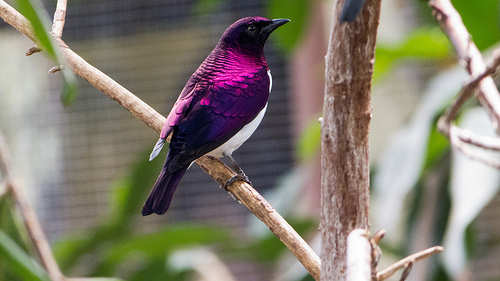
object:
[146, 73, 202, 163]
wing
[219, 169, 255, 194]
foot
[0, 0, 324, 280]
branch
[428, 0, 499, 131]
branch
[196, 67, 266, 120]
wing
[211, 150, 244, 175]
leg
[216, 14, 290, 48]
head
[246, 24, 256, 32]
eye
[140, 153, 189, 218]
tail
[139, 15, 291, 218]
bird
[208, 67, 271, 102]
breast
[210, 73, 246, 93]
feathers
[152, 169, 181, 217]
feathers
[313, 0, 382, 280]
stalk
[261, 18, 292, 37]
beak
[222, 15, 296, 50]
bird's face